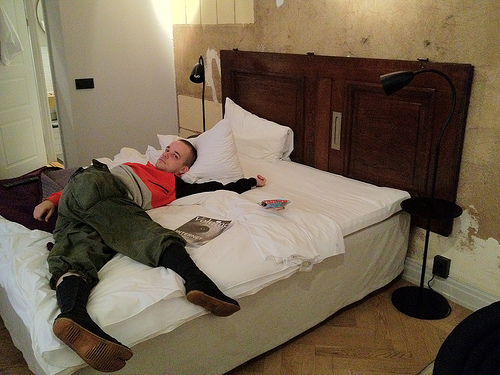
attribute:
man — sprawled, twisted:
[32, 140, 266, 374]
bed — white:
[1, 141, 412, 374]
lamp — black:
[380, 66, 463, 320]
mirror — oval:
[36, 1, 44, 32]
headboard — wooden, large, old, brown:
[219, 49, 473, 236]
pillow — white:
[223, 98, 294, 162]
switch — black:
[76, 79, 94, 89]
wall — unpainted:
[172, 4, 222, 142]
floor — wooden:
[223, 279, 472, 374]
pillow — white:
[181, 119, 244, 185]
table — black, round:
[436, 300, 500, 373]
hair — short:
[179, 140, 198, 169]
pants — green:
[48, 164, 188, 288]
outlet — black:
[431, 269, 438, 277]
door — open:
[0, 2, 47, 183]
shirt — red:
[108, 160, 177, 205]